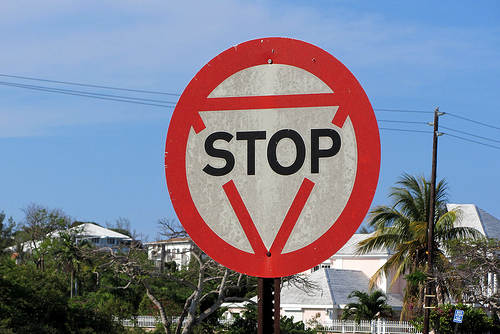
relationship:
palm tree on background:
[358, 169, 471, 329] [348, 209, 491, 276]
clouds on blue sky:
[0, 0, 500, 134] [363, 3, 496, 79]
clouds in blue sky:
[71, 42, 161, 62] [0, 0, 500, 221]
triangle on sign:
[182, 87, 360, 256] [164, 36, 379, 279]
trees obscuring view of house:
[16, 239, 209, 329] [23, 218, 130, 287]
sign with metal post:
[164, 36, 382, 279] [235, 260, 307, 329]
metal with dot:
[254, 277, 281, 332] [269, 289, 275, 294]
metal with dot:
[254, 277, 281, 332] [269, 299, 275, 303]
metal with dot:
[254, 277, 281, 332] [270, 307, 275, 311]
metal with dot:
[254, 277, 281, 332] [269, 316, 275, 320]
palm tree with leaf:
[349, 170, 487, 333] [396, 177, 438, 210]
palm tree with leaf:
[349, 170, 487, 333] [368, 206, 415, 231]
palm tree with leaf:
[349, 170, 487, 333] [358, 220, 413, 253]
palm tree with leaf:
[349, 170, 487, 333] [434, 226, 481, 249]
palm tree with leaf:
[349, 170, 487, 333] [433, 175, 448, 226]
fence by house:
[308, 317, 421, 332] [226, 267, 408, 329]